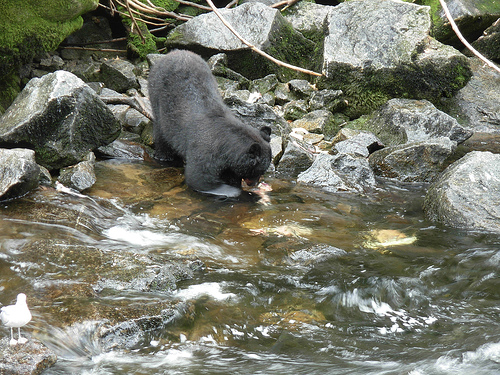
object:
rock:
[0, 70, 121, 172]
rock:
[320, 0, 473, 96]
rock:
[168, 0, 316, 88]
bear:
[146, 48, 273, 197]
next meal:
[218, 189, 262, 202]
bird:
[0, 292, 33, 345]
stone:
[0, 340, 55, 375]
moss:
[328, 56, 473, 116]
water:
[201, 257, 498, 375]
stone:
[23, 182, 95, 237]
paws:
[203, 184, 242, 198]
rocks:
[424, 148, 500, 231]